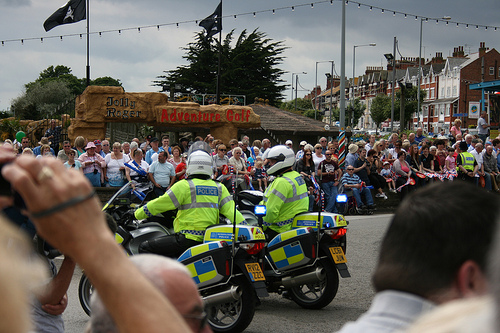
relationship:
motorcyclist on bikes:
[233, 144, 310, 308] [214, 174, 351, 311]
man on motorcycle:
[126, 149, 249, 262] [77, 180, 265, 330]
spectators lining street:
[1, 108, 499, 215] [49, 210, 390, 330]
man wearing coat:
[126, 149, 249, 262] [133, 177, 250, 243]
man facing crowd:
[454, 140, 478, 180] [1, 112, 498, 213]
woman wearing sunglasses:
[296, 147, 315, 186] [301, 150, 312, 158]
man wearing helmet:
[126, 149, 249, 262] [186, 150, 214, 178]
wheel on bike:
[205, 270, 257, 331] [78, 181, 267, 330]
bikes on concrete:
[79, 174, 350, 331] [51, 210, 395, 330]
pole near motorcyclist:
[333, 10, 350, 180] [233, 144, 310, 308]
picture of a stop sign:
[11, 10, 484, 317] [245, 236, 269, 266]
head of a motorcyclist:
[260, 140, 299, 178] [233, 144, 310, 308]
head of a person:
[180, 149, 214, 177] [130, 150, 253, 252]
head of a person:
[129, 145, 145, 165] [126, 146, 148, 177]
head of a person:
[109, 138, 125, 156] [107, 140, 127, 172]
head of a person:
[86, 141, 96, 156] [77, 138, 106, 182]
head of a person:
[100, 140, 109, 153] [100, 140, 113, 156]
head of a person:
[344, 160, 355, 175] [340, 161, 375, 211]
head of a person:
[322, 147, 333, 164] [319, 148, 338, 195]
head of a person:
[380, 156, 390, 170] [382, 160, 394, 187]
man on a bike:
[126, 149, 249, 262] [77, 180, 270, 332]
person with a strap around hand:
[5, 153, 197, 323] [8, 148, 109, 248]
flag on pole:
[197, 5, 226, 35] [210, 31, 224, 113]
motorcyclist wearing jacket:
[256, 142, 311, 239] [257, 169, 309, 233]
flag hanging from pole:
[42, 0, 87, 32] [85, 1, 91, 82]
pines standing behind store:
[148, 26, 294, 109] [71, 81, 353, 144]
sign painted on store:
[159, 105, 252, 123] [65, 83, 354, 149]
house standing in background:
[419, 40, 484, 134] [2, 1, 480, 149]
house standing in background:
[382, 50, 445, 136] [2, 1, 480, 149]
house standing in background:
[347, 61, 387, 136] [2, 1, 480, 149]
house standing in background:
[311, 73, 349, 116] [2, 1, 480, 149]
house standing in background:
[300, 83, 323, 113] [2, 1, 480, 149]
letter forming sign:
[158, 106, 169, 123] [159, 105, 252, 123]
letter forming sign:
[167, 105, 178, 121] [159, 105, 252, 123]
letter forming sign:
[200, 110, 210, 120] [159, 105, 252, 123]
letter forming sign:
[222, 107, 235, 121] [159, 105, 252, 123]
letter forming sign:
[244, 108, 250, 122] [159, 105, 252, 123]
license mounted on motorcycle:
[245, 262, 267, 282] [77, 180, 265, 330]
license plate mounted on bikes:
[327, 243, 346, 264] [214, 174, 351, 311]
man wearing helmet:
[126, 149, 249, 262] [182, 137, 216, 179]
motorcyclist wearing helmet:
[233, 144, 310, 308] [260, 143, 297, 175]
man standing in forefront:
[332, 177, 478, 331] [1, 136, 484, 329]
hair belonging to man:
[370, 179, 498, 299] [332, 177, 478, 331]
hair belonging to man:
[370, 179, 480, 300] [332, 177, 478, 331]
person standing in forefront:
[0, 143, 193, 333] [1, 136, 484, 329]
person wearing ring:
[0, 143, 193, 333] [34, 162, 54, 180]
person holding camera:
[0, 143, 193, 333] [2, 161, 32, 225]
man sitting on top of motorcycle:
[126, 149, 249, 262] [77, 180, 265, 330]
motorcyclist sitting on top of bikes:
[233, 144, 310, 308] [214, 174, 351, 311]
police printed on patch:
[193, 187, 220, 195] [192, 183, 219, 195]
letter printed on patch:
[195, 186, 201, 194] [192, 183, 219, 195]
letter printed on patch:
[200, 186, 207, 194] [192, 183, 219, 195]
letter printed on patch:
[202, 188, 209, 195] [192, 183, 219, 195]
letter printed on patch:
[208, 188, 214, 194] [192, 183, 219, 195]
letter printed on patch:
[212, 187, 219, 195] [192, 183, 219, 195]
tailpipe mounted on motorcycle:
[199, 280, 243, 309] [77, 180, 265, 330]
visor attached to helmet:
[184, 140, 213, 160] [182, 149, 215, 181]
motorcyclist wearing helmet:
[233, 144, 310, 308] [258, 141, 302, 171]